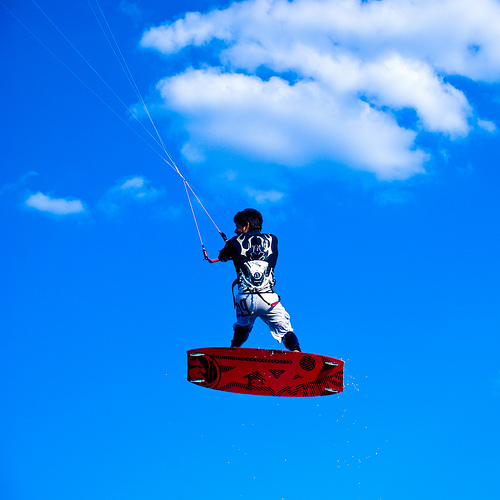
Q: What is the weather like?
A: It is cloudless.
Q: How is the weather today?
A: It is cloudless.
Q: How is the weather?
A: It is cloudless.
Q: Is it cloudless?
A: Yes, it is cloudless.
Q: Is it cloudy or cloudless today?
A: It is cloudless.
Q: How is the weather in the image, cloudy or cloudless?
A: It is cloudless.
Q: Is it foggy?
A: No, it is cloudless.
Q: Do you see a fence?
A: No, there are no fences.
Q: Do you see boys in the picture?
A: No, there are no boys.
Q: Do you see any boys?
A: No, there are no boys.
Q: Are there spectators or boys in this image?
A: No, there are no boys or spectators.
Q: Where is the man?
A: The man is in the sky.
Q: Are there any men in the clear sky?
A: Yes, there is a man in the sky.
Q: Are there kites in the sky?
A: No, there is a man in the sky.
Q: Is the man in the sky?
A: Yes, the man is in the sky.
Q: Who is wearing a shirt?
A: The man is wearing a shirt.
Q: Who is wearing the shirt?
A: The man is wearing a shirt.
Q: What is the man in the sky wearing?
A: The man is wearing a shirt.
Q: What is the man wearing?
A: The man is wearing a shirt.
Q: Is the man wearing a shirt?
A: Yes, the man is wearing a shirt.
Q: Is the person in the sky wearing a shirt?
A: Yes, the man is wearing a shirt.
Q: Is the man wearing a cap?
A: No, the man is wearing a shirt.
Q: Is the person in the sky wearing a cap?
A: No, the man is wearing a shirt.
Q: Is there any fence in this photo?
A: No, there are no fences.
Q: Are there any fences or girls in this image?
A: No, there are no fences or girls.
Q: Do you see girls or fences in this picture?
A: No, there are no fences or girls.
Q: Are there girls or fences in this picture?
A: No, there are no fences or girls.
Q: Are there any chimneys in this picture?
A: No, there are no chimneys.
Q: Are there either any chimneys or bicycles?
A: No, there are no chimneys or bicycles.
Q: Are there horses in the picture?
A: No, there are no horses.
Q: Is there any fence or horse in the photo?
A: No, there are no horses or fences.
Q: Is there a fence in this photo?
A: No, there are no fences.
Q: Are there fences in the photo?
A: No, there are no fences.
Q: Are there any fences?
A: No, there are no fences.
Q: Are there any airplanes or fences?
A: No, there are no fences or airplanes.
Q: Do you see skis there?
A: No, there are no skis.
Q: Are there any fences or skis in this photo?
A: No, there are no skis or fences.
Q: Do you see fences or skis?
A: No, there are no skis or fences.